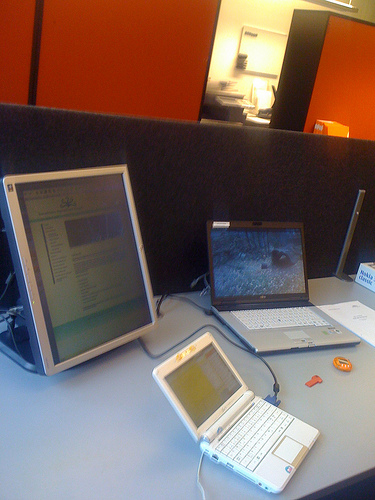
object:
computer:
[150, 329, 319, 492]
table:
[0, 270, 374, 500]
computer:
[0, 160, 158, 376]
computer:
[205, 219, 361, 357]